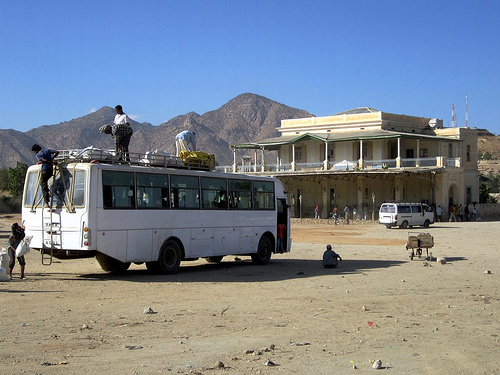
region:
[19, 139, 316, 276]
white bus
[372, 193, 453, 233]
white minivan parked outside building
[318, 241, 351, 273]
person sitting on ground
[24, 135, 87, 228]
man standing on ladder at back of bus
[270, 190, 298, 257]
open door of bus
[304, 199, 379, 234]
people standing outside building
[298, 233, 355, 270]
man sitting in shadow of bus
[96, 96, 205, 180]
man standing on roof of bus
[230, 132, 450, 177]
balcony on building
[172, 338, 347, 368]
rocks on road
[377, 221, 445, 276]
shopping buggy used for hauling items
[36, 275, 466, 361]
dirt road with several large rocks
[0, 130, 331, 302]
large white travel van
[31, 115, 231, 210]
three people standing on the white travel van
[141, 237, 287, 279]
two large black tires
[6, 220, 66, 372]
one person handing a package to the person standing on van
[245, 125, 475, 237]
large saloon type building with people standing in front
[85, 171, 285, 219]
several windows in a large white van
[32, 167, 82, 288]
silver ladder on the back of a white van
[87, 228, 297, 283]
storage units in the bottom of the white van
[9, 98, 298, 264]
a white passenger bus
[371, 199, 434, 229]
a white passenger van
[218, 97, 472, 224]
a two story building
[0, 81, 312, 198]
a line of mountains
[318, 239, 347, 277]
a person sitting on the ground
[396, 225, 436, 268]
a cart with items in it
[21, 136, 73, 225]
a man standing on a latter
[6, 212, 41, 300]
a person holding a white bag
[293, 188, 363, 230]
three people in front of a building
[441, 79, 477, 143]
a communications towers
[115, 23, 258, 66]
this is the sky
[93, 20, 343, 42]
the sky is blue in color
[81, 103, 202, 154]
these are people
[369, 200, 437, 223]
this is a van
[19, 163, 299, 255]
this is a bus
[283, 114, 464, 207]
this is abuilding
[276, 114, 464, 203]
the building is tall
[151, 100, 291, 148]
this is a mountain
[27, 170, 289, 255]
the bus is white in color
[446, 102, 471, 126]
this is a satelite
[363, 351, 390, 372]
a rock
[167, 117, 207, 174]
a person that is bending down to pick something up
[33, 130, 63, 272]
a ladder on a bus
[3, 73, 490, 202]
mountains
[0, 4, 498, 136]
the blue sky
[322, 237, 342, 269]
a person that is sitting in the shade made by the bus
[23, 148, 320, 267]
a white bus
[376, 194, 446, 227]
a white van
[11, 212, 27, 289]
a person that is passing bags to a person on the bus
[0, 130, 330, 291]
the bus